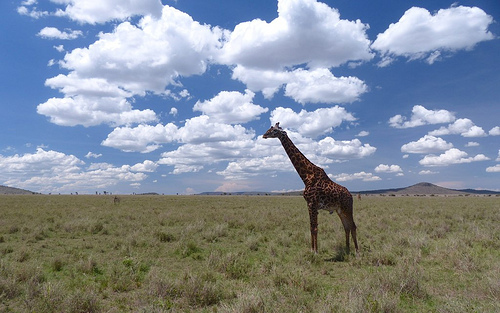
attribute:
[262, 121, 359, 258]
giraffe — standing, tall, grazing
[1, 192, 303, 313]
tall grass — green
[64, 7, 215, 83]
clouds — white